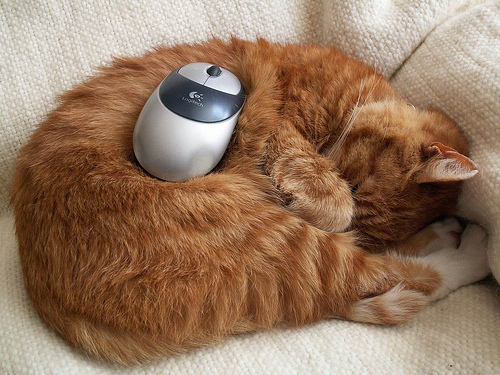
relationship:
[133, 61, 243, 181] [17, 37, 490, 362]
mouse on cat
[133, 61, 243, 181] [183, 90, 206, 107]
mouse has logo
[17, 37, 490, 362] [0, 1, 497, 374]
cat on couch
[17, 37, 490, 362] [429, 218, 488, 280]
cat has toes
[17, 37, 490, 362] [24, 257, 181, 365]
cat has tail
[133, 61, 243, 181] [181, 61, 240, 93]
mouse has buttons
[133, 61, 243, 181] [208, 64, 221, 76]
mouse has scroll-wheel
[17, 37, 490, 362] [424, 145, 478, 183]
cat has ears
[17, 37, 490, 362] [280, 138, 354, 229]
cat has paw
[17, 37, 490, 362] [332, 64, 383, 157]
cat has whiskers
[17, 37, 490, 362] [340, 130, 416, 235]
cat has face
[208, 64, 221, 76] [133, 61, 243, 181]
scroll-wheel of mouse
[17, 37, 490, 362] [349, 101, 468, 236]
cat has head